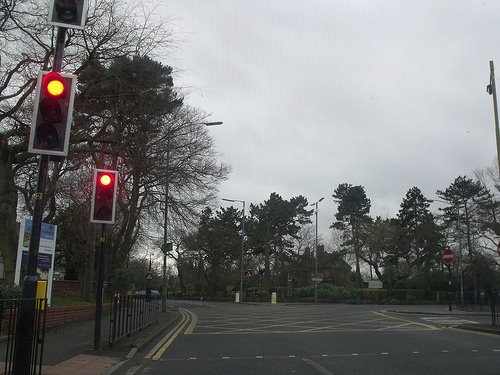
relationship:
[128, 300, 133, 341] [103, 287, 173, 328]
opening in gate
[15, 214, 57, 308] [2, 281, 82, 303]
sign on grass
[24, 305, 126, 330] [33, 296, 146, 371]
brick wall by sidewalk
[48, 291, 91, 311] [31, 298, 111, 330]
grass by brick wall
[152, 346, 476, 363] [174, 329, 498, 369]
dots on ground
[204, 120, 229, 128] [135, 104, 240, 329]
light on pole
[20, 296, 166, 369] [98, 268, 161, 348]
sidewalk behind fence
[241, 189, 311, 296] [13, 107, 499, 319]
trees in background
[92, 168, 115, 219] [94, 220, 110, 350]
light on pole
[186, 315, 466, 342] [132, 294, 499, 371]
lines on ground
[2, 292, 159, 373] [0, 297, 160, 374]
black fence along sidewalk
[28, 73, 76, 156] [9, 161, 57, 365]
light on pole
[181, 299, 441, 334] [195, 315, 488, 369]
lines on ground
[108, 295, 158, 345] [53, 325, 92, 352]
railing along sidewalk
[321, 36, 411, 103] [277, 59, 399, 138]
cloud on sky